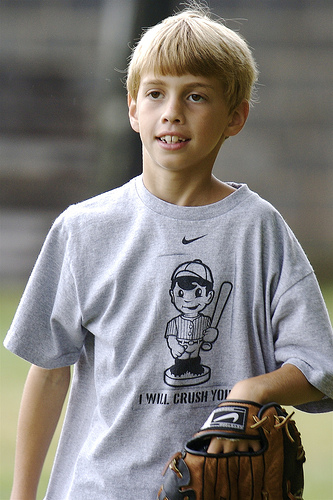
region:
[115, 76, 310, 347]
a boy and his glove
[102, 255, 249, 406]
the boy has a logo on his shirt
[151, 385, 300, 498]
a glove is on the boy's hand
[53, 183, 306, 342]
the shirt is gray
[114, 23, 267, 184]
he looks very young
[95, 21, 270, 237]
the child looks happy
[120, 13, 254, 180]
this boy is content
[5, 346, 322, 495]
the child's arms is in the shot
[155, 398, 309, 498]
A brown leather baseball glove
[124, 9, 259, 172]
Blonde hair on boy's head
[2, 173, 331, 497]
A gray colored shirt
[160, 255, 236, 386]
Picture of a boy holding a bat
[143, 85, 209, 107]
A pair of brown eyes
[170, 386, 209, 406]
The word "CRUSH" printed on a shirt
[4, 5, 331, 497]
Young boy is wearing a baseball glove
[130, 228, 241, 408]
Design on a gray shirt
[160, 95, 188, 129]
Nose on boy's face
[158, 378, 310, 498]
Glove on a boy's hand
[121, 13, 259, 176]
The boy has blonde hair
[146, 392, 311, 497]
A brown leather glove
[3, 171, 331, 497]
A gray short sleeved shirt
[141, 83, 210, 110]
Two eyes are brown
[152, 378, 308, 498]
A baseball glove on a hand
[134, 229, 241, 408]
A design on the shirt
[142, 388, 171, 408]
The word "WILL" on a shirt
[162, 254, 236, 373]
Picture of a boy holding baseball bat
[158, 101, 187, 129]
Nose on boy's face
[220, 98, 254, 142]
Ear on boy's head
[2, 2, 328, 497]
boy wearing a glove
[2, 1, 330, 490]
boy wearing gray t-shirt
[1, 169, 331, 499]
Grayt-shirt with baseball player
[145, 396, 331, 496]
Brown and black baseball glove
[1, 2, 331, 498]
Boy with blonde hair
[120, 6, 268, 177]
boy with brown eyes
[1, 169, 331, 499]
T-shirt with black lettering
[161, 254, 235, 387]
baseball player holding a bat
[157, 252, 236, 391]
baseball player decal wearing a hat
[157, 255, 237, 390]
baseball decal wearing a uniform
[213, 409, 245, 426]
a famous sport logo on a baseball mitt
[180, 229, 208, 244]
a spirts wesr logo on grey t-shirt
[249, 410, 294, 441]
leather laceon baseball mitt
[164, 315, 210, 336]
a striped baseball jersey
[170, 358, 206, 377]
cleats on black shoes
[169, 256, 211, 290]
a baseball cap on black hair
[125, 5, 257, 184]
a young boy with blond hair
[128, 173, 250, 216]
neck of t-shirt pulled to one side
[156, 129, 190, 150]
mouth of a boy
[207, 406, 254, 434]
emblem on a glove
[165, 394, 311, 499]
a brown leather glove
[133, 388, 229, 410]
black text on a shirt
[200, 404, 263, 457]
hand of a boy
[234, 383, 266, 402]
wrist of a boy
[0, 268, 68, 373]
sleeve of a shirt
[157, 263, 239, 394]
picture of a ball player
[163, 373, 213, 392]
base under a child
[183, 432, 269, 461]
hole in a glove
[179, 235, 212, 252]
The blue check on the shirt.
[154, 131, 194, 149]
The boys open mouth.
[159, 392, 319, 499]
The baseball mitt on the left hand.